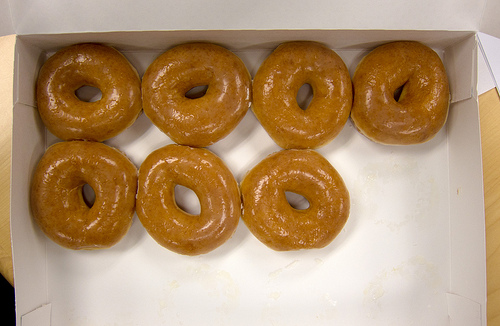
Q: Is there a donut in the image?
A: Yes, there is a donut.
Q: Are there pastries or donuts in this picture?
A: Yes, there is a donut.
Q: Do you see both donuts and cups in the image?
A: No, there is a donut but no cups.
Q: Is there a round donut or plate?
A: Yes, there is a round donut.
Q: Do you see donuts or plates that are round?
A: Yes, the donut is round.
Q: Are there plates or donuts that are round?
A: Yes, the donut is round.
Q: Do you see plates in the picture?
A: No, there are no plates.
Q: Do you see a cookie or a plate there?
A: No, there are no plates or cookies.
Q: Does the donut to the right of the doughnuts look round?
A: Yes, the doughnut is round.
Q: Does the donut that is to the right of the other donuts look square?
A: No, the donut is round.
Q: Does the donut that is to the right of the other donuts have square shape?
A: No, the donut is round.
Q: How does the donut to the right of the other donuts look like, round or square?
A: The donut is round.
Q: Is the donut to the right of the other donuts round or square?
A: The donut is round.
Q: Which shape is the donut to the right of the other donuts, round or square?
A: The donut is round.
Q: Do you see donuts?
A: Yes, there is a donut.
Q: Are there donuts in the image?
A: Yes, there is a donut.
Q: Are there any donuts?
A: Yes, there is a donut.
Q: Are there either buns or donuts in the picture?
A: Yes, there is a donut.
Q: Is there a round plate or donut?
A: Yes, there is a round donut.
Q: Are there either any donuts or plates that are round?
A: Yes, the donut is round.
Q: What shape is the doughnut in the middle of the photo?
A: The donut is round.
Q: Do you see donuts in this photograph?
A: Yes, there is a donut.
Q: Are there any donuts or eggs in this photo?
A: Yes, there is a donut.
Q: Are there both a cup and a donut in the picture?
A: No, there is a donut but no cups.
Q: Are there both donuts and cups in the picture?
A: No, there is a donut but no cups.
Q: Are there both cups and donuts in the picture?
A: No, there is a donut but no cups.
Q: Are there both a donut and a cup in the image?
A: No, there is a donut but no cups.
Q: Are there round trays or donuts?
A: Yes, there is a round donut.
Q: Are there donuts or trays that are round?
A: Yes, the donut is round.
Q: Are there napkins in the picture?
A: No, there are no napkins.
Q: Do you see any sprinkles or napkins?
A: No, there are no napkins or sprinkles.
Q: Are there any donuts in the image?
A: Yes, there are donuts.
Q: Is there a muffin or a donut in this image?
A: Yes, there are donuts.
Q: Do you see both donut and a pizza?
A: No, there are donuts but no pizzas.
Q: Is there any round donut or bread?
A: Yes, there are round donuts.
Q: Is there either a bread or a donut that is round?
A: Yes, the donuts are round.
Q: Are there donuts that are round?
A: Yes, there are round donuts.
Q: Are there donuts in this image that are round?
A: Yes, there are donuts that are round.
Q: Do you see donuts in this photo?
A: Yes, there is a donut.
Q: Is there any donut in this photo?
A: Yes, there is a donut.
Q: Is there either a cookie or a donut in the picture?
A: Yes, there is a donut.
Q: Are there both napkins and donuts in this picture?
A: No, there is a donut but no napkins.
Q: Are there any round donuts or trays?
A: Yes, there is a round donut.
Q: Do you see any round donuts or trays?
A: Yes, there is a round donut.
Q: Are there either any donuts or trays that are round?
A: Yes, the donut is round.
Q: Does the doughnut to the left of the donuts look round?
A: Yes, the doughnut is round.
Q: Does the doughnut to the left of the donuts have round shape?
A: Yes, the doughnut is round.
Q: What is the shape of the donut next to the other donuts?
A: The donut is round.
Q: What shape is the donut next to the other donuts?
A: The donut is round.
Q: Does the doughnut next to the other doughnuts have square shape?
A: No, the donut is round.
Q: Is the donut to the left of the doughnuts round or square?
A: The donut is round.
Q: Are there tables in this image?
A: Yes, there is a table.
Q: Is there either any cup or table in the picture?
A: Yes, there is a table.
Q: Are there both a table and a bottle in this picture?
A: No, there is a table but no bottles.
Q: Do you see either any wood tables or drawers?
A: Yes, there is a wood table.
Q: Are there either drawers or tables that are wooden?
A: Yes, the table is wooden.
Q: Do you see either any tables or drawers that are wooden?
A: Yes, the table is wooden.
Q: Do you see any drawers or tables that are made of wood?
A: Yes, the table is made of wood.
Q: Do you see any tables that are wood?
A: Yes, there is a wood table.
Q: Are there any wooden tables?
A: Yes, there is a wood table.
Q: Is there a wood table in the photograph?
A: Yes, there is a wood table.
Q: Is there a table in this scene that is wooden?
A: Yes, there is a table that is wooden.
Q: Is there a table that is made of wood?
A: Yes, there is a table that is made of wood.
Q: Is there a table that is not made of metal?
A: Yes, there is a table that is made of wood.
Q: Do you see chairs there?
A: No, there are no chairs.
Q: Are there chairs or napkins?
A: No, there are no chairs or napkins.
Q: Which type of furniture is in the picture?
A: The furniture is a table.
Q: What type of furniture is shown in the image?
A: The furniture is a table.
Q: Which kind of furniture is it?
A: The piece of furniture is a table.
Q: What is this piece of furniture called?
A: This is a table.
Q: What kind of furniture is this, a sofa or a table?
A: This is a table.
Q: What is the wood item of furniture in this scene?
A: The piece of furniture is a table.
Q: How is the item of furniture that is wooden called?
A: The piece of furniture is a table.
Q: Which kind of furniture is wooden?
A: The furniture is a table.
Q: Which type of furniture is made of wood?
A: The furniture is a table.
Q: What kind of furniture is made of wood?
A: The furniture is a table.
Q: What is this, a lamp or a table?
A: This is a table.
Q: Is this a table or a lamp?
A: This is a table.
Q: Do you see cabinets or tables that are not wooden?
A: No, there is a table but it is wooden.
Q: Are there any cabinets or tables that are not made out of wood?
A: No, there is a table but it is made of wood.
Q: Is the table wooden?
A: Yes, the table is wooden.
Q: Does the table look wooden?
A: Yes, the table is wooden.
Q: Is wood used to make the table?
A: Yes, the table is made of wood.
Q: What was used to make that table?
A: The table is made of wood.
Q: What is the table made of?
A: The table is made of wood.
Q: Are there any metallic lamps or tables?
A: No, there is a table but it is wooden.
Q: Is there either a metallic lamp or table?
A: No, there is a table but it is wooden.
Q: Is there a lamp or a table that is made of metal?
A: No, there is a table but it is made of wood.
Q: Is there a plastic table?
A: No, there is a table but it is made of wood.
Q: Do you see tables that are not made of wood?
A: No, there is a table but it is made of wood.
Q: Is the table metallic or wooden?
A: The table is wooden.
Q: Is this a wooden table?
A: Yes, this is a wooden table.